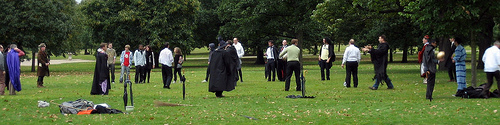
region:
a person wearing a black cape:
[200, 44, 240, 99]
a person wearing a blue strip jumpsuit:
[449, 32, 470, 93]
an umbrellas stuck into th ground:
[176, 76, 190, 103]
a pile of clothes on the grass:
[57, 92, 122, 123]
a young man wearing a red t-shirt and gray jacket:
[118, 40, 130, 80]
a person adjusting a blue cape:
[1, 43, 23, 97]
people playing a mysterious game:
[11, 36, 492, 116]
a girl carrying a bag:
[174, 47, 185, 76]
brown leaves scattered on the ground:
[273, 105, 450, 123]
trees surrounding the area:
[3, 1, 488, 46]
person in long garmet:
[92, 38, 118, 100]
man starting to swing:
[276, 29, 301, 98]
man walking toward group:
[362, 30, 391, 103]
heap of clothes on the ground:
[45, 97, 113, 117]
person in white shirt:
[158, 44, 168, 76]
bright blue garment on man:
[5, 45, 25, 95]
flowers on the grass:
[255, 102, 352, 124]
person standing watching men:
[31, 31, 51, 91]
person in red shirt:
[121, 26, 128, 78]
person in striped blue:
[452, 36, 466, 105]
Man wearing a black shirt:
[364, 29, 397, 92]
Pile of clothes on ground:
[37, 96, 118, 116]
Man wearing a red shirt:
[111, 40, 136, 85]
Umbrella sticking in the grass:
[112, 78, 135, 115]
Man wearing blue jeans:
[364, 34, 401, 99]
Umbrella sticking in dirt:
[292, 65, 317, 100]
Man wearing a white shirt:
[479, 41, 499, 91]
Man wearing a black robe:
[204, 36, 239, 102]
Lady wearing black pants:
[312, 29, 340, 85]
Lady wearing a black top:
[171, 40, 191, 84]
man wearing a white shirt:
[157, 43, 173, 88]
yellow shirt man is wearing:
[278, 45, 298, 60]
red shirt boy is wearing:
[123, 50, 128, 65]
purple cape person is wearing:
[5, 48, 21, 89]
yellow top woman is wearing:
[318, 42, 329, 58]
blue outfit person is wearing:
[452, 48, 465, 94]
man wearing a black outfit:
[35, 40, 50, 85]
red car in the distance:
[361, 43, 371, 51]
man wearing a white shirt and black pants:
[341, 36, 358, 86]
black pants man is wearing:
[285, 60, 302, 91]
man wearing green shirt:
[280, 44, 310, 63]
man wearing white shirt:
[341, 41, 363, 67]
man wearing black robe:
[198, 54, 245, 93]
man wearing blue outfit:
[450, 47, 474, 89]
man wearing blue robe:
[6, 49, 26, 78]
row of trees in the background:
[1, 0, 484, 34]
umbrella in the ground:
[175, 70, 202, 104]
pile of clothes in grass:
[47, 88, 103, 124]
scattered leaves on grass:
[248, 96, 373, 121]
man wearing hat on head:
[37, 42, 55, 62]